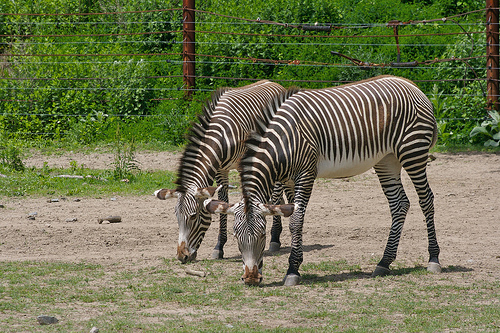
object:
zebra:
[150, 67, 287, 265]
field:
[0, 145, 499, 331]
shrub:
[112, 72, 219, 146]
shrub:
[49, 112, 171, 144]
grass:
[22, 250, 100, 301]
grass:
[203, 279, 308, 321]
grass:
[387, 288, 472, 320]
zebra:
[233, 59, 443, 281]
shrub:
[440, 16, 469, 81]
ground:
[459, 162, 489, 226]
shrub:
[93, 49, 162, 114]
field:
[34, 285, 478, 330]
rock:
[36, 312, 63, 328]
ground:
[40, 322, 74, 331]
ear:
[152, 184, 179, 198]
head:
[159, 178, 218, 245]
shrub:
[9, 74, 132, 144]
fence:
[26, 27, 492, 179]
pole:
[145, 27, 441, 108]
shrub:
[102, 139, 151, 180]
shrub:
[1, 139, 38, 172]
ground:
[2, 114, 495, 321]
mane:
[237, 85, 302, 211]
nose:
[250, 274, 257, 281]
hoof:
[280, 266, 303, 287]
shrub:
[424, 78, 487, 145]